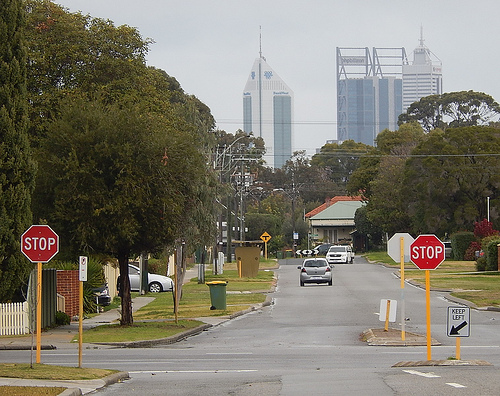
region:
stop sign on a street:
[415, 227, 456, 358]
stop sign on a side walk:
[25, 218, 55, 365]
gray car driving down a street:
[297, 251, 332, 293]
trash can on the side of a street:
[202, 262, 229, 317]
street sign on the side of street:
[441, 292, 478, 348]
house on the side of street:
[307, 183, 372, 244]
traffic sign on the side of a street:
[253, 218, 272, 257]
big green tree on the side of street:
[70, 114, 222, 324]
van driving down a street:
[320, 243, 351, 268]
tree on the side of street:
[397, 115, 492, 226]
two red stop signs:
[3, 195, 481, 380]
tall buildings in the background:
[220, 19, 495, 221]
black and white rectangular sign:
[438, 300, 476, 380]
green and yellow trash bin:
[197, 267, 244, 319]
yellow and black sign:
[249, 222, 277, 264]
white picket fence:
[0, 294, 54, 348]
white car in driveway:
[110, 238, 186, 303]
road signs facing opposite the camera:
[356, 222, 413, 327]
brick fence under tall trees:
[45, 259, 92, 318]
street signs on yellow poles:
[17, 215, 475, 376]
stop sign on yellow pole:
[408, 228, 451, 362]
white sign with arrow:
[440, 301, 477, 344]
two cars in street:
[297, 234, 359, 294]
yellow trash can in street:
[202, 275, 233, 313]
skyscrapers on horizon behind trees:
[225, 41, 446, 171]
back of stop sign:
[382, 228, 414, 273]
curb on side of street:
[175, 323, 215, 342]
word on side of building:
[266, 85, 293, 101]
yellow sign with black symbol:
[252, 225, 279, 247]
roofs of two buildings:
[299, 192, 363, 232]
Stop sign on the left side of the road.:
[17, 222, 62, 265]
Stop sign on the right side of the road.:
[409, 230, 446, 273]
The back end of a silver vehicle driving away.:
[295, 258, 332, 285]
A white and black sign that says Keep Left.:
[446, 304, 471, 338]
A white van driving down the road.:
[324, 244, 354, 264]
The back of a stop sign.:
[385, 231, 415, 263]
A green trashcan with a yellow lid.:
[202, 278, 229, 310]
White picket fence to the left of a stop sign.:
[0, 300, 31, 336]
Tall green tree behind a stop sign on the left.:
[37, 84, 217, 325]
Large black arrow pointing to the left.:
[447, 318, 468, 339]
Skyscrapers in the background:
[173, 17, 438, 202]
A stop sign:
[395, 222, 459, 377]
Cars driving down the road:
[264, 185, 395, 322]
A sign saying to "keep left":
[425, 297, 481, 359]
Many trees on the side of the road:
[14, 8, 176, 228]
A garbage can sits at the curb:
[197, 267, 236, 325]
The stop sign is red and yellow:
[404, 229, 451, 372]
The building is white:
[212, 10, 306, 262]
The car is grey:
[291, 248, 338, 299]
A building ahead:
[290, 187, 381, 264]